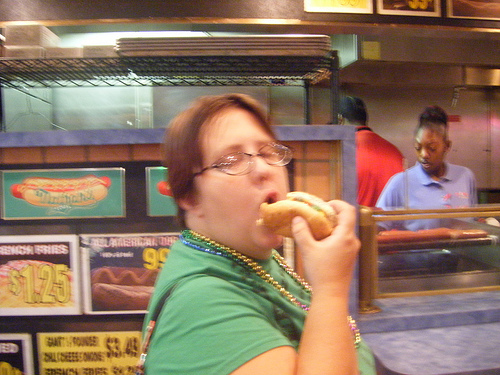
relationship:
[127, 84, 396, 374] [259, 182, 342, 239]
person eating hotdog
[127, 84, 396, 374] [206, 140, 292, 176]
person wearing eyeglasses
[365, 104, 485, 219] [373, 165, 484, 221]
lady in blue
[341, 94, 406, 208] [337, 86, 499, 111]
person in back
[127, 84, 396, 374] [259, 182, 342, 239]
person eating hot dog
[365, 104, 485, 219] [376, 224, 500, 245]
person serving food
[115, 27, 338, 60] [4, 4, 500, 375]
trays in restaurant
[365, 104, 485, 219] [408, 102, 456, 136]
lady with hair up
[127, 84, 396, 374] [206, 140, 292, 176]
person wearing glasses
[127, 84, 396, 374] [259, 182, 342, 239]
person holding hotdog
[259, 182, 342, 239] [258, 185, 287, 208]
hotdog in mouth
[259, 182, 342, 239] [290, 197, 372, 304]
hotdog in a hand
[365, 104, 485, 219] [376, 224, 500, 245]
girl working with food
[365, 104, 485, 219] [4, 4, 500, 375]
employees in restaurant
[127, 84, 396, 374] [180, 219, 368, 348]
person wearing necklaces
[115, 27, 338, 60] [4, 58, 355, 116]
trays are on a shelf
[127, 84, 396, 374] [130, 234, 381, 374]
woman wearing green shirt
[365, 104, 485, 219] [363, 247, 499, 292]
woman looking down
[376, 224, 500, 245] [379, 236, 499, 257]
hot dogs are on top of grills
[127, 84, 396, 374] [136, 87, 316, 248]
woman with short hair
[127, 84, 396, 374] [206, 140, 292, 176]
person eating hot dog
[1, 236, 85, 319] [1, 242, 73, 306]
ad of french fries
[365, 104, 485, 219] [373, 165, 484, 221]
lady in blue shirt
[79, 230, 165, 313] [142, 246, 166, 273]
hot dog costing about one dollar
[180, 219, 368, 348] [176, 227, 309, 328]
beads in various colors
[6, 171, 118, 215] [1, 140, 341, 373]
sign on wall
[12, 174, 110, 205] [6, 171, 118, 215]
hot dog on sign